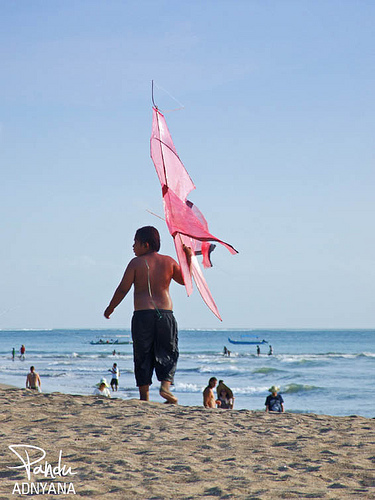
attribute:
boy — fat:
[103, 224, 193, 408]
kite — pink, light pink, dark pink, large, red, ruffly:
[142, 77, 242, 323]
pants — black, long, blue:
[130, 312, 181, 386]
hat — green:
[216, 379, 230, 395]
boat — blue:
[226, 337, 268, 346]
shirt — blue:
[217, 399, 227, 410]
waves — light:
[52, 357, 90, 375]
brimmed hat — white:
[94, 377, 111, 387]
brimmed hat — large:
[267, 386, 279, 394]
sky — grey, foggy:
[2, 3, 372, 330]